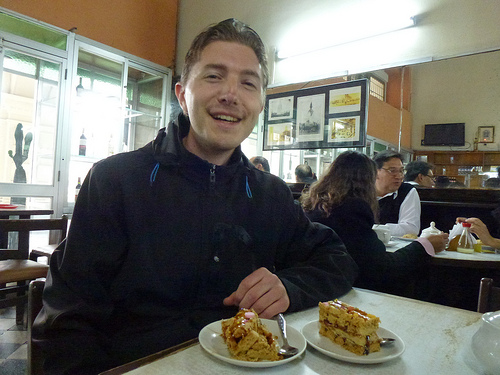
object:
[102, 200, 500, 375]
table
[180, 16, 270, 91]
short hair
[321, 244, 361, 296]
elbow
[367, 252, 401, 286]
elbow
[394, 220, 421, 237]
elbow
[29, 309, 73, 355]
elbow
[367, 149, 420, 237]
man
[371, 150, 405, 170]
hair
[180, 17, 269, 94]
hair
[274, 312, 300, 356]
spoon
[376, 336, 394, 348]
spoon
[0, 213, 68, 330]
chair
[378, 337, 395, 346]
silver spoon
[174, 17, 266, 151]
head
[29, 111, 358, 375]
jacket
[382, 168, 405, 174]
glasses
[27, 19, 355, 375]
person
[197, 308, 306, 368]
plate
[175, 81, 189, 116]
ear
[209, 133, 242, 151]
jaw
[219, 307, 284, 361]
food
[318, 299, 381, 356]
food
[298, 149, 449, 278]
people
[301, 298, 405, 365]
plate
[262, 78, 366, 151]
picture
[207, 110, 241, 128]
mouth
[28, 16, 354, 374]
man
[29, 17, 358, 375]
people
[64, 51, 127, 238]
door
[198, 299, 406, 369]
diner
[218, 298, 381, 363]
meal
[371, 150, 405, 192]
man's head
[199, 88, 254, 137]
smile